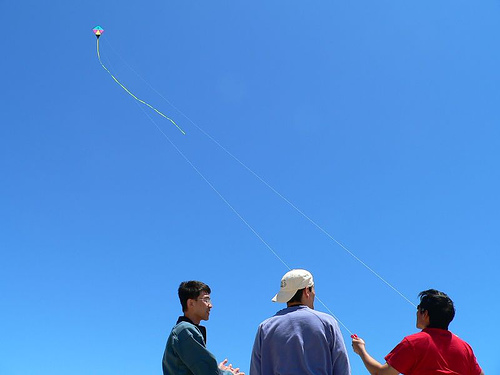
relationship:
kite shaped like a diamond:
[92, 25, 188, 143] [93, 26, 102, 39]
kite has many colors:
[92, 25, 188, 143] [94, 23, 103, 39]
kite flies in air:
[92, 25, 188, 143] [1, 0, 496, 266]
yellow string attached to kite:
[94, 38, 185, 135] [92, 25, 188, 143]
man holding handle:
[350, 288, 486, 373] [347, 329, 358, 346]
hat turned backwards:
[273, 267, 316, 306] [266, 303, 333, 374]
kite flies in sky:
[92, 25, 188, 143] [1, 0, 496, 266]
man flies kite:
[350, 288, 486, 373] [92, 25, 188, 143]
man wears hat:
[250, 267, 352, 374] [273, 267, 316, 306]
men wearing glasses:
[160, 277, 245, 375] [192, 293, 214, 306]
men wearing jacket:
[160, 277, 245, 375] [162, 313, 239, 373]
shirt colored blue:
[248, 307, 353, 373] [266, 303, 333, 374]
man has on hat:
[250, 267, 352, 374] [273, 267, 316, 306]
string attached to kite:
[97, 35, 423, 336] [92, 25, 188, 143]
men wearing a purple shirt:
[160, 277, 245, 375] [162, 313, 239, 373]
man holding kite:
[350, 288, 486, 373] [92, 25, 188, 143]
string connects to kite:
[97, 35, 423, 336] [92, 25, 188, 143]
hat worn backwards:
[273, 267, 316, 306] [266, 303, 333, 374]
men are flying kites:
[160, 267, 490, 374] [92, 25, 188, 143]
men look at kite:
[160, 267, 490, 374] [92, 25, 188, 143]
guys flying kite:
[160, 267, 490, 374] [92, 25, 188, 143]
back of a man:
[266, 303, 333, 374] [250, 267, 352, 374]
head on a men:
[176, 278, 214, 325] [160, 277, 245, 375]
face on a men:
[199, 288, 212, 322] [160, 277, 245, 375]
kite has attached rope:
[92, 25, 188, 143] [97, 35, 423, 336]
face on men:
[199, 288, 212, 322] [160, 277, 245, 375]